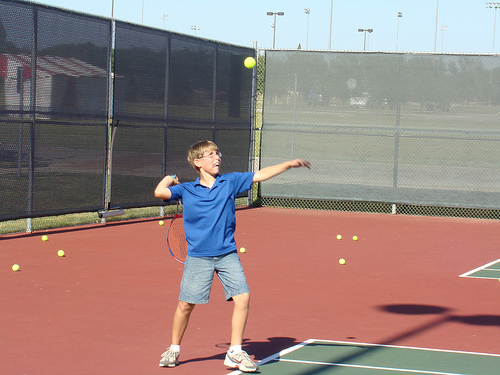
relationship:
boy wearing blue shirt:
[152, 140, 309, 373] [166, 170, 256, 256]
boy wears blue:
[152, 140, 309, 373] [167, 169, 259, 306]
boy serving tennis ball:
[152, 140, 309, 373] [242, 55, 257, 71]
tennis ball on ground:
[337, 256, 347, 265] [0, 204, 499, 374]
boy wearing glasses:
[152, 140, 309, 373] [195, 149, 223, 160]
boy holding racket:
[152, 140, 309, 373] [165, 173, 187, 262]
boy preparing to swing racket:
[152, 140, 309, 373] [165, 174, 186, 265]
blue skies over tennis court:
[1, 0, 499, 375] [37, 1, 499, 56]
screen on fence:
[9, 10, 173, 166] [3, 2, 498, 216]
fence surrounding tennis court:
[3, 2, 498, 216] [3, 199, 498, 374]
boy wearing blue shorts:
[152, 140, 309, 373] [173, 243, 251, 310]